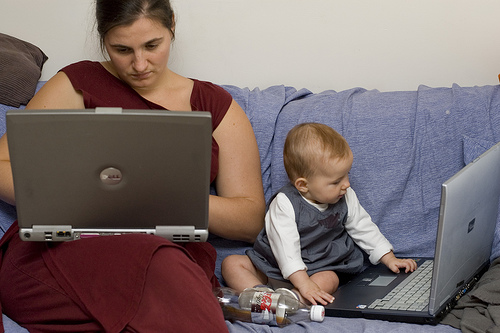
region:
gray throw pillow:
[2, 23, 63, 113]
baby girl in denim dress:
[235, 114, 375, 323]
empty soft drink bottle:
[225, 280, 336, 332]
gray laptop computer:
[6, 98, 225, 260]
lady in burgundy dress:
[12, 0, 266, 331]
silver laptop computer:
[356, 142, 495, 328]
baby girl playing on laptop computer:
[261, 111, 490, 328]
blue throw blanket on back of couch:
[332, 78, 489, 197]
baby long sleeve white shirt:
[257, 178, 411, 275]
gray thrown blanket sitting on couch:
[415, 242, 497, 329]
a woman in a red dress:
[0, 6, 248, 327]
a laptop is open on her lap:
[3, 17, 219, 328]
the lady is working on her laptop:
[3, 1, 259, 256]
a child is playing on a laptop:
[222, 123, 487, 323]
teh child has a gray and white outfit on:
[247, 151, 390, 276]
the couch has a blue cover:
[5, 81, 495, 327]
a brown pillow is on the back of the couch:
[0, 35, 45, 110]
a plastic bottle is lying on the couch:
[235, 282, 323, 327]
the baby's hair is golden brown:
[282, 121, 352, 207]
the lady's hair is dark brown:
[94, 1, 181, 88]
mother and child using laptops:
[47, 18, 473, 304]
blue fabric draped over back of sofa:
[226, 70, 491, 251]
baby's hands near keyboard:
[275, 125, 460, 320]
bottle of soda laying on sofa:
[200, 275, 337, 325]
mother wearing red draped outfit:
[40, 55, 255, 316]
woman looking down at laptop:
[75, 10, 196, 87]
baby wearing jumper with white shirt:
[261, 110, 408, 300]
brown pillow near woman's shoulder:
[5, 31, 50, 106]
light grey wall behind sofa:
[255, 30, 475, 116]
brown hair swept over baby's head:
[278, 105, 363, 210]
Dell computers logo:
[88, 156, 137, 189]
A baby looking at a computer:
[258, 118, 405, 326]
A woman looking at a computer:
[17, 15, 244, 254]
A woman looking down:
[38, 2, 208, 103]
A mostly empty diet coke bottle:
[197, 288, 344, 323]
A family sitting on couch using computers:
[11, 11, 498, 318]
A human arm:
[200, 78, 275, 245]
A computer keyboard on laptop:
[404, 258, 434, 312]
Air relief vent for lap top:
[160, 218, 215, 254]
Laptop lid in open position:
[426, 115, 498, 294]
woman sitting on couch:
[1, 2, 267, 331]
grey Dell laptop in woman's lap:
[4, 105, 214, 244]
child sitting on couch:
[233, 123, 367, 314]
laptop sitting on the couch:
[328, 147, 498, 322]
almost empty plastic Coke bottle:
[215, 284, 327, 330]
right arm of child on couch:
[262, 194, 331, 304]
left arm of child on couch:
[348, 189, 415, 273]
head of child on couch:
[283, 119, 353, 208]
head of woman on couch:
[87, 0, 180, 90]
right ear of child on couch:
[293, 175, 311, 195]